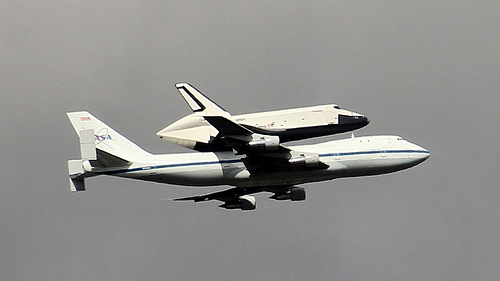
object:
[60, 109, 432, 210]
plane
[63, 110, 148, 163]
tail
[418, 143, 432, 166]
nose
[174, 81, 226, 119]
tail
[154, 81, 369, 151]
space shuttle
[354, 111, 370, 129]
nose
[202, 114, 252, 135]
wing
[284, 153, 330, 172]
engine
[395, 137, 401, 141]
windshield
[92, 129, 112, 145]
logo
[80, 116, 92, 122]
flag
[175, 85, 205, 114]
lines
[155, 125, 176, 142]
point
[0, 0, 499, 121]
sky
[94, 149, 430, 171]
stripe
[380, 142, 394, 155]
door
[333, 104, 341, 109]
window